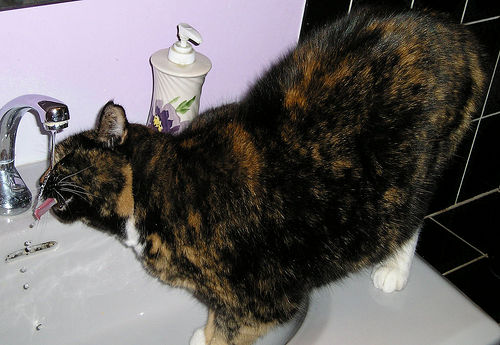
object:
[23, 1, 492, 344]
cat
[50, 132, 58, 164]
water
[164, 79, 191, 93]
liquid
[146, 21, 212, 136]
bottle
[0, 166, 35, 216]
steel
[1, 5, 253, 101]
wall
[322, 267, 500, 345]
washbasin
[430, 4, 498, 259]
tiles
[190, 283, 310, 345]
leg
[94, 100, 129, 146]
ear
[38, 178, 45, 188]
nose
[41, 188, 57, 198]
mustache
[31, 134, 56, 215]
facuet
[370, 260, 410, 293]
white feet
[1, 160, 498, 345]
sink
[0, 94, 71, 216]
tap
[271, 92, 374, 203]
fur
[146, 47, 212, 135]
soap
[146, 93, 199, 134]
flowered design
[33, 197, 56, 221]
tongue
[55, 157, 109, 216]
whiskers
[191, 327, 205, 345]
white paw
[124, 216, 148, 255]
white patch